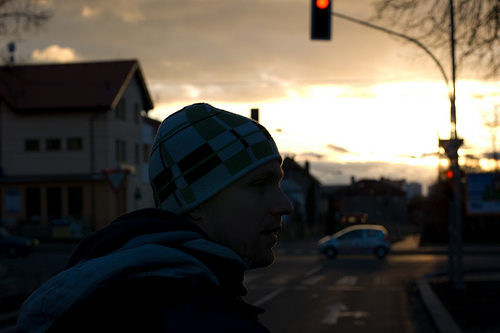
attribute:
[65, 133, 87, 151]
window — small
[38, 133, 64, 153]
window — small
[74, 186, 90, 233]
window — small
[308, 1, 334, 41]
light — red, for street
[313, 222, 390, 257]
car — small, silver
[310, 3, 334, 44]
light — red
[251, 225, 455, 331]
street — painted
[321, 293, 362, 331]
arrow — white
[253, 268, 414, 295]
crosswalk — lines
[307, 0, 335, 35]
light — red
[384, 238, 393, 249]
tail light — red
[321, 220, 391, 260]
car — silver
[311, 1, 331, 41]
traffic light — red glow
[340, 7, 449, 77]
pole — curved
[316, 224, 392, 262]
car — small, silver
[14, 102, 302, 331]
man — profile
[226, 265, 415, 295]
lines — white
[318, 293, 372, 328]
arrow — white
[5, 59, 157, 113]
roof — curved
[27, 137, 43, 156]
window — square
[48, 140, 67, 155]
window — square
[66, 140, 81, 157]
window — square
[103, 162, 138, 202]
sign — triangle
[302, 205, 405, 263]
car — silver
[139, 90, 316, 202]
cap — black and white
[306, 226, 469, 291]
vehicle — light color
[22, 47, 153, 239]
building — 2 story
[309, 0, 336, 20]
traffic light — red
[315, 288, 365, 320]
arrows — white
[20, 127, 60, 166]
window — small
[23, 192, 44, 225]
window — small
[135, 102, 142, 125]
window — small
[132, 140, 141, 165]
window — small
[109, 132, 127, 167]
window — small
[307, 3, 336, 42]
light — street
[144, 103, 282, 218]
cap — knit, multicolored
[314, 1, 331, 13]
light — red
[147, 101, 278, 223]
hat — white, black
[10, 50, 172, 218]
building — one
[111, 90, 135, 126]
window — small